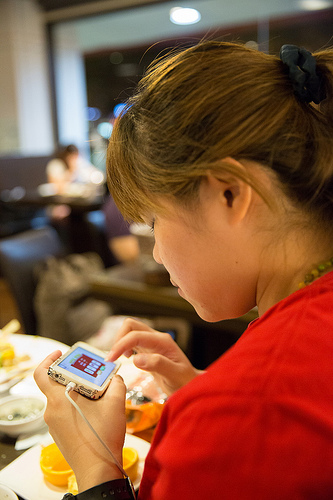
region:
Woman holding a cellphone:
[30, 32, 331, 499]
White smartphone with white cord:
[48, 339, 140, 499]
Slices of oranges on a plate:
[38, 440, 139, 494]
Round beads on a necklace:
[290, 254, 332, 289]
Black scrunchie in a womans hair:
[277, 41, 331, 104]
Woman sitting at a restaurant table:
[43, 140, 89, 197]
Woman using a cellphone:
[30, 35, 331, 498]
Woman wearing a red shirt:
[31, 34, 331, 498]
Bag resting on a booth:
[1, 224, 181, 356]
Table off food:
[0, 319, 169, 497]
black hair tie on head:
[281, 40, 325, 107]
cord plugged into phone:
[57, 377, 87, 401]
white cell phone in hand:
[54, 343, 122, 397]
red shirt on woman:
[151, 284, 328, 499]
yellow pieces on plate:
[35, 444, 69, 484]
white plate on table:
[8, 451, 47, 498]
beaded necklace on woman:
[289, 259, 324, 301]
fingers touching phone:
[24, 308, 163, 431]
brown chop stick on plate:
[0, 311, 20, 337]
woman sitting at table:
[40, 139, 94, 207]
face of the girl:
[90, 118, 303, 328]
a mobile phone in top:
[39, 342, 121, 390]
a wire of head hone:
[71, 391, 141, 473]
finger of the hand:
[108, 375, 132, 410]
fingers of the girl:
[30, 342, 64, 377]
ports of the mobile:
[48, 356, 115, 410]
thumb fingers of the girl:
[110, 316, 174, 390]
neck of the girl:
[258, 244, 319, 313]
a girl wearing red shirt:
[164, 353, 324, 493]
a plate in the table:
[2, 314, 65, 436]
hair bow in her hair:
[279, 38, 327, 107]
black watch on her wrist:
[58, 473, 138, 497]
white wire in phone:
[58, 381, 84, 415]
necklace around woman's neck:
[295, 262, 330, 297]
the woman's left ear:
[198, 158, 263, 228]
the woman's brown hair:
[113, 31, 329, 162]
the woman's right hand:
[110, 313, 197, 391]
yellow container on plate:
[36, 446, 73, 486]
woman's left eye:
[143, 215, 161, 229]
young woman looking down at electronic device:
[37, 43, 324, 398]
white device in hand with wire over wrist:
[37, 336, 137, 492]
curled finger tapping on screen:
[57, 318, 171, 382]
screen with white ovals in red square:
[51, 342, 117, 393]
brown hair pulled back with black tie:
[97, 30, 327, 320]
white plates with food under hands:
[0, 319, 209, 493]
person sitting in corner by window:
[1, 63, 105, 232]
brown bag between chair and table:
[1, 204, 157, 326]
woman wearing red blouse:
[133, 123, 326, 493]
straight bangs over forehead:
[99, 96, 181, 258]